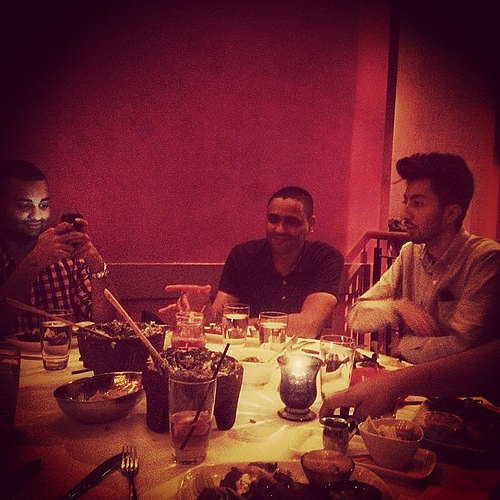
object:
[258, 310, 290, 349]
glass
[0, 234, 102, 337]
shirt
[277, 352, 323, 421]
candle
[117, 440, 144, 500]
fork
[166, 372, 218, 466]
glass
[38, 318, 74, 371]
glass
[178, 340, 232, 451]
straw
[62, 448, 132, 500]
fork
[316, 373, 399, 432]
hand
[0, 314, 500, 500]
table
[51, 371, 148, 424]
bowl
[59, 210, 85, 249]
phone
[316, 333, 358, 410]
cup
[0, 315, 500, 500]
ambiance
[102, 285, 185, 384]
spoon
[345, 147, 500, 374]
man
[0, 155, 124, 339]
friends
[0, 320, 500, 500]
meal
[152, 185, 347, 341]
gentlement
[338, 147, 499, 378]
gentlement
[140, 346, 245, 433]
food